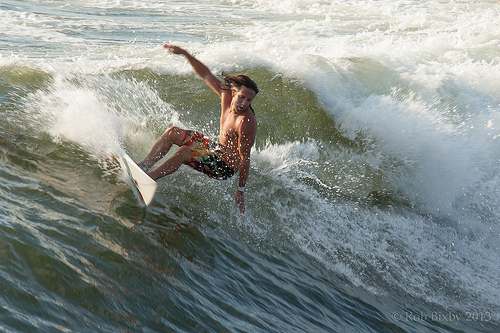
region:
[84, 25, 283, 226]
Surfer on the sea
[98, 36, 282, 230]
Surfer without top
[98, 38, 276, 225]
Surfer with white surfer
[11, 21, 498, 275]
Surfer on waves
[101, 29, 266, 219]
Surer wearing a colored short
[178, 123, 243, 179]
Multicolored short of surfer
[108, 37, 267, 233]
Surfer wearing a watch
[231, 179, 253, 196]
Watch in a left hand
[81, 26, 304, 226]
Surfer with arms open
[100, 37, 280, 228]
Surfer looking to the side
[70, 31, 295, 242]
A man surfing on a wave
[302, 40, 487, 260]
A wave breaking in the ocean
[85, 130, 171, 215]
A white surfboard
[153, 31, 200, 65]
A man's hand while surfing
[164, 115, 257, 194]
colorful swim trunks on a surfer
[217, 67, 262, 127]
A man's head while surfing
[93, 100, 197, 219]
feet riding on a surfboard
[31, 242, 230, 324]
Ocean water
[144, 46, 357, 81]
The crest of a wave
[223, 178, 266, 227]
A man's hand with a watch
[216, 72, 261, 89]
brown hair of the surfing man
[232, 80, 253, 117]
the face of the surfing man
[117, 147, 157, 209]
the white underside of a surfboard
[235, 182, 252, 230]
a hand barely above the water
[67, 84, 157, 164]
surf created by the surfboard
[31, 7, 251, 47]
calmer water behind the wave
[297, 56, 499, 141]
the part of the wave that is breaking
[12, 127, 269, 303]
the calm rising part of the wave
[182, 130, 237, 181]
the red and black shorts of the surfer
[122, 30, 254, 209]
a man surfing a wave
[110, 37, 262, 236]
a man surfing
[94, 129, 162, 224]
a white surfboard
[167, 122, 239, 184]
colorful shorts on a man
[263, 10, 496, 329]
ocean waves splashing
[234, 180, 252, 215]
a white wristband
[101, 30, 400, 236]
a man surfing ocean waves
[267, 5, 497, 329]
an ocean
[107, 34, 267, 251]
a man surfing in colorful shorts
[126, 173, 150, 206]
a red an blue logo on a surfboard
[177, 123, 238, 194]
colorful shorts with bold black lines